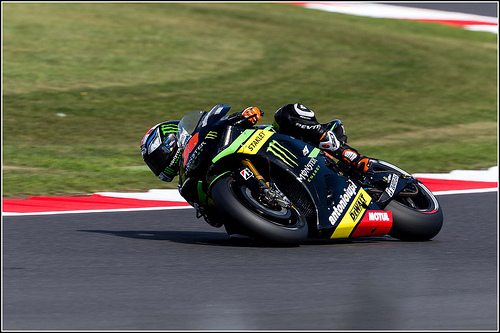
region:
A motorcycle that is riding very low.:
[175, 102, 442, 249]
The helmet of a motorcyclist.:
[137, 116, 192, 185]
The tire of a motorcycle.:
[207, 168, 309, 246]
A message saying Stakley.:
[243, 127, 270, 154]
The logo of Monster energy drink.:
[203, 127, 220, 141]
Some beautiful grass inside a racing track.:
[1, 0, 497, 201]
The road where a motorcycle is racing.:
[1, 192, 497, 328]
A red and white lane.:
[2, 169, 498, 216]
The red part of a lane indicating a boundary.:
[1, 193, 190, 210]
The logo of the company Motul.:
[366, 210, 390, 222]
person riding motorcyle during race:
[118, 91, 449, 242]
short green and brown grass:
[12, 114, 65, 168]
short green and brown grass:
[64, 121, 103, 160]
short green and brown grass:
[19, 85, 61, 134]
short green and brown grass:
[96, 86, 122, 143]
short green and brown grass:
[9, 38, 53, 82]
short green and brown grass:
[202, 43, 263, 88]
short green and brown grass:
[384, 120, 441, 150]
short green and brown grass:
[445, 98, 485, 140]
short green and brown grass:
[349, 65, 409, 105]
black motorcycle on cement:
[122, 82, 457, 252]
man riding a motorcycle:
[125, 87, 447, 249]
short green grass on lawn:
[36, 10, 494, 152]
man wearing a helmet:
[131, 113, 216, 202]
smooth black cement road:
[10, 205, 497, 330]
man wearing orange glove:
[135, 103, 278, 185]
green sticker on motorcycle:
[256, 131, 328, 193]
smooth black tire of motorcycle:
[198, 166, 326, 255]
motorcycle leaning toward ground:
[175, 108, 448, 247]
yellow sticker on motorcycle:
[321, 188, 387, 241]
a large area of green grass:
[2, 3, 498, 190]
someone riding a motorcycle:
[140, 98, 445, 241]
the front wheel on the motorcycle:
[216, 166, 306, 242]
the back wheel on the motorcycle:
[370, 160, 443, 236]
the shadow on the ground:
[84, 220, 271, 248]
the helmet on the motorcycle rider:
[138, 116, 187, 179]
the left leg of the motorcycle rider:
[257, 113, 378, 177]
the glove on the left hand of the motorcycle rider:
[236, 106, 261, 123]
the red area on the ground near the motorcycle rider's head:
[3, 191, 185, 221]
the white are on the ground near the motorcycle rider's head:
[102, 185, 194, 202]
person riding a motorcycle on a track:
[102, 80, 442, 255]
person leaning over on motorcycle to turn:
[129, 113, 456, 247]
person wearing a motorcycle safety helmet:
[125, 106, 212, 190]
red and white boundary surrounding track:
[42, 183, 172, 221]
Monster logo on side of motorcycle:
[257, 131, 318, 186]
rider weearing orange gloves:
[230, 101, 265, 128]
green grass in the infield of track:
[35, 17, 140, 170]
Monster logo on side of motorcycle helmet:
[152, 120, 184, 140]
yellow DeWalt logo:
[331, 185, 367, 236]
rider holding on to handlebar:
[214, 90, 270, 142]